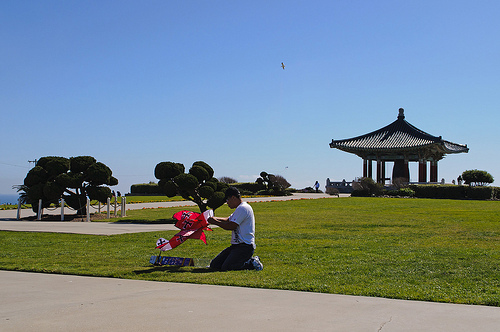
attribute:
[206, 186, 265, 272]
man — kneeling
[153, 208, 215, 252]
kite — red, black, white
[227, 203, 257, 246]
t-shirt — white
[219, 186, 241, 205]
baseball cap — black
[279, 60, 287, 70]
bird — flying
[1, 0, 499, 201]
sky — blue, clear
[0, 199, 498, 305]
grass — green, short, brown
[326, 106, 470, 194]
pagoda — chinese, gray, covered